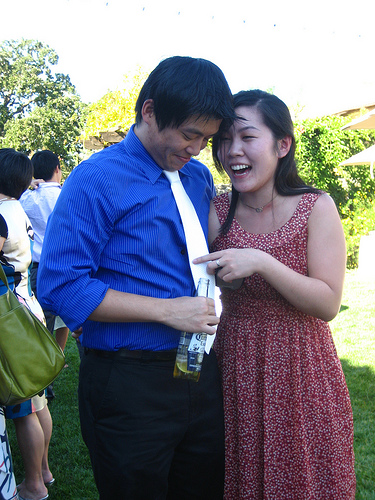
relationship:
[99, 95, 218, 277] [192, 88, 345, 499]
man with people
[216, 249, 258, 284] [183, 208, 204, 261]
hand holding tie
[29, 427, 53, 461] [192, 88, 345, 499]
calf of people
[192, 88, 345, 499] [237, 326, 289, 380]
people wearing dress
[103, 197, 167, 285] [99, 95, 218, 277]
shirt on man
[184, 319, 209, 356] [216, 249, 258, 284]
bottle in hand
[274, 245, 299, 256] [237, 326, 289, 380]
dots are on dress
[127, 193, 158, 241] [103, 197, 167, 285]
stripes are on shirt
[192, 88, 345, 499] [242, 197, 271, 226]
people wearing necklace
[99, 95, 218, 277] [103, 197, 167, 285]
man wearing shirt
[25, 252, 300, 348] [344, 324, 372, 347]
people are on grass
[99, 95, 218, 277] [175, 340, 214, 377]
man holding beer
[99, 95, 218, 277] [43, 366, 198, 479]
man wearing pants